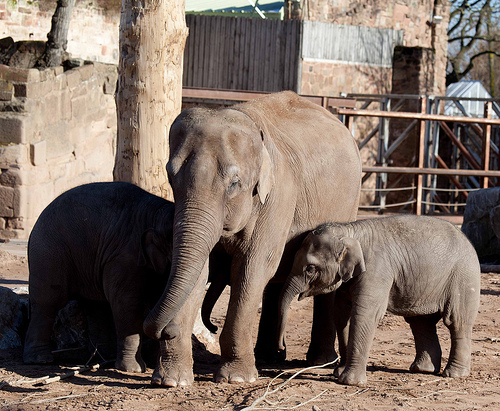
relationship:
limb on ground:
[235, 354, 343, 411] [0, 243, 499, 410]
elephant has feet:
[273, 213, 479, 390] [330, 363, 368, 389]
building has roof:
[440, 81, 499, 214] [440, 81, 499, 122]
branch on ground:
[235, 354, 343, 411] [0, 243, 499, 410]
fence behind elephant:
[180, 13, 301, 105] [143, 88, 364, 388]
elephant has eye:
[273, 213, 479, 390] [305, 264, 316, 274]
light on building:
[432, 15, 443, 26] [296, 1, 451, 207]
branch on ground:
[41, 358, 116, 386] [0, 243, 499, 410]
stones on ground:
[397, 401, 413, 408] [0, 243, 499, 410]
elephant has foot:
[143, 88, 364, 388] [149, 363, 196, 388]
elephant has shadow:
[143, 88, 364, 388] [0, 180, 310, 393]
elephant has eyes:
[143, 88, 364, 388] [166, 167, 243, 197]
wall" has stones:
[3, 37, 118, 243] [1, 37, 49, 70]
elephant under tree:
[143, 88, 364, 388] [112, 0, 189, 206]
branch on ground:
[6, 358, 116, 396] [0, 243, 499, 410]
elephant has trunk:
[143, 88, 364, 388] [141, 198, 225, 342]